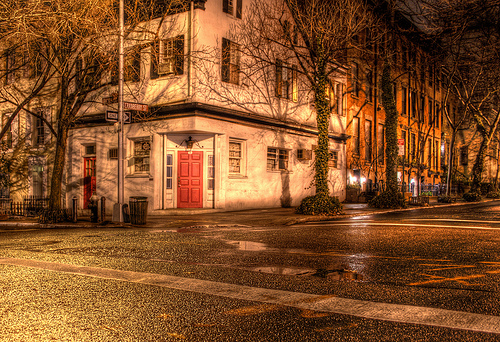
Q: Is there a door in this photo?
A: Yes, there is a door.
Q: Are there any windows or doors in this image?
A: Yes, there is a door.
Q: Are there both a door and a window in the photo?
A: Yes, there are both a door and a window.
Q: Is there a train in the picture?
A: No, there are no trains.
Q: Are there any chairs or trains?
A: No, there are no trains or chairs.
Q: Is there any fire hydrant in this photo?
A: Yes, there is a fire hydrant.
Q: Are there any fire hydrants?
A: Yes, there is a fire hydrant.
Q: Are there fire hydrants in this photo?
A: Yes, there is a fire hydrant.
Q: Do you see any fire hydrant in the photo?
A: Yes, there is a fire hydrant.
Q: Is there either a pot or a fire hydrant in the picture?
A: Yes, there is a fire hydrant.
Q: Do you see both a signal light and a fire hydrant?
A: No, there is a fire hydrant but no traffic lights.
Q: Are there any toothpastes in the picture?
A: No, there are no toothpastes.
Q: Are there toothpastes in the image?
A: No, there are no toothpastes.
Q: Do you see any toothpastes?
A: No, there are no toothpastes.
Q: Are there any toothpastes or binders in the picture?
A: No, there are no toothpastes or binders.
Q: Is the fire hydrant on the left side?
A: Yes, the fire hydrant is on the left of the image.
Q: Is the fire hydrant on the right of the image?
A: No, the fire hydrant is on the left of the image.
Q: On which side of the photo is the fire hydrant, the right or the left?
A: The fire hydrant is on the left of the image.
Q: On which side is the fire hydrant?
A: The fire hydrant is on the left of the image.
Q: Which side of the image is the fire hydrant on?
A: The fire hydrant is on the left of the image.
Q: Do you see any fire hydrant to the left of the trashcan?
A: Yes, there is a fire hydrant to the left of the trashcan.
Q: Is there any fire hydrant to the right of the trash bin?
A: No, the fire hydrant is to the left of the trash bin.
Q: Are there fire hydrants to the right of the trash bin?
A: No, the fire hydrant is to the left of the trash bin.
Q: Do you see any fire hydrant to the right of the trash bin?
A: No, the fire hydrant is to the left of the trash bin.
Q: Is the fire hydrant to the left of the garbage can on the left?
A: Yes, the fire hydrant is to the left of the trash bin.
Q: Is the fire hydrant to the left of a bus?
A: No, the fire hydrant is to the left of the trash bin.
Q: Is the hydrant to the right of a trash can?
A: No, the hydrant is to the left of a trash can.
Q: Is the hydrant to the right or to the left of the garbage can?
A: The hydrant is to the left of the garbage can.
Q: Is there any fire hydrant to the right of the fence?
A: Yes, there is a fire hydrant to the right of the fence.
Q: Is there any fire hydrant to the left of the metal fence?
A: No, the fire hydrant is to the right of the fence.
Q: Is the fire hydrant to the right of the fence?
A: Yes, the fire hydrant is to the right of the fence.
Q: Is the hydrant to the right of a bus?
A: No, the hydrant is to the right of the fence.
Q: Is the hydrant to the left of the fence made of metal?
A: No, the hydrant is to the right of the fence.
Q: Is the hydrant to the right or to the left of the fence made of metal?
A: The hydrant is to the right of the fence.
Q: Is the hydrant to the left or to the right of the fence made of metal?
A: The hydrant is to the right of the fence.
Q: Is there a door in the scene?
A: Yes, there is a door.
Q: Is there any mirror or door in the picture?
A: Yes, there is a door.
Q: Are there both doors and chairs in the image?
A: No, there is a door but no chairs.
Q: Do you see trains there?
A: No, there are no trains.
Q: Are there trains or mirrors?
A: No, there are no trains or mirrors.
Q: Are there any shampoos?
A: No, there are no shampoos.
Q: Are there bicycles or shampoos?
A: No, there are no shampoos or bicycles.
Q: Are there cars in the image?
A: No, there are no cars.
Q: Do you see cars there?
A: No, there are no cars.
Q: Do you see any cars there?
A: No, there are no cars.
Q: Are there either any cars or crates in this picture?
A: No, there are no cars or crates.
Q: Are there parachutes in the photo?
A: No, there are no parachutes.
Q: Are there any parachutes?
A: No, there are no parachutes.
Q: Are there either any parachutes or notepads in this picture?
A: No, there are no parachutes or notepads.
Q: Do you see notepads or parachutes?
A: No, there are no parachutes or notepads.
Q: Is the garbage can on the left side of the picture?
A: Yes, the garbage can is on the left of the image.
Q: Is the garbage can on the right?
A: No, the garbage can is on the left of the image.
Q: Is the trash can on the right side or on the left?
A: The trash can is on the left of the image.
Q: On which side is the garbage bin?
A: The garbage bin is on the left of the image.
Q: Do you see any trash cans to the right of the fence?
A: Yes, there is a trash can to the right of the fence.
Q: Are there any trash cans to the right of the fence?
A: Yes, there is a trash can to the right of the fence.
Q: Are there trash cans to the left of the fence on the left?
A: No, the trash can is to the right of the fence.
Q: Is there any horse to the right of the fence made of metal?
A: No, there is a trash can to the right of the fence.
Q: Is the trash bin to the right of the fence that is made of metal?
A: Yes, the trash bin is to the right of the fence.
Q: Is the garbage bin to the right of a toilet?
A: No, the garbage bin is to the right of the fence.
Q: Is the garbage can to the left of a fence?
A: No, the garbage can is to the right of a fence.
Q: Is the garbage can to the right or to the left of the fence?
A: The garbage can is to the right of the fence.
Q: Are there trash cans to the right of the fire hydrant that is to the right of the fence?
A: Yes, there is a trash can to the right of the fire hydrant.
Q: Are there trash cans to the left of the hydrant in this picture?
A: No, the trash can is to the right of the hydrant.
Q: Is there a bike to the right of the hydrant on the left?
A: No, there is a trash can to the right of the hydrant.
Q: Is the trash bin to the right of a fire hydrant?
A: Yes, the trash bin is to the right of a fire hydrant.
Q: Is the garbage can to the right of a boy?
A: No, the garbage can is to the right of a fire hydrant.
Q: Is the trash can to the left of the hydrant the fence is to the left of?
A: No, the trash can is to the right of the fire hydrant.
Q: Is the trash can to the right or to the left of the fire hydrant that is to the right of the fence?
A: The trash can is to the right of the fire hydrant.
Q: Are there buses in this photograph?
A: No, there are no buses.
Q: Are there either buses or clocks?
A: No, there are no buses or clocks.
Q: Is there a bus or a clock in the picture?
A: No, there are no buses or clocks.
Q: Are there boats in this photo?
A: No, there are no boats.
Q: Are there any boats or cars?
A: No, there are no boats or cars.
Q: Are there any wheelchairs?
A: No, there are no wheelchairs.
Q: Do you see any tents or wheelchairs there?
A: No, there are no wheelchairs or tents.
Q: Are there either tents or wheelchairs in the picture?
A: No, there are no wheelchairs or tents.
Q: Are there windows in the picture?
A: Yes, there are windows.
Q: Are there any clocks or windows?
A: Yes, there are windows.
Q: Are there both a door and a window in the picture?
A: Yes, there are both a window and a door.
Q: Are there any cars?
A: No, there are no cars.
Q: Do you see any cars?
A: No, there are no cars.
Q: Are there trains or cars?
A: No, there are no cars or trains.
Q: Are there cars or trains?
A: No, there are no cars or trains.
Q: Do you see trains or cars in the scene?
A: No, there are no cars or trains.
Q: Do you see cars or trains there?
A: No, there are no cars or trains.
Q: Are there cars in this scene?
A: No, there are no cars.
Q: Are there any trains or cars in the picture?
A: No, there are no cars or trains.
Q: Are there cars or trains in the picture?
A: No, there are no cars or trains.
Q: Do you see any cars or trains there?
A: No, there are no cars or trains.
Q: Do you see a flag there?
A: No, there are no flags.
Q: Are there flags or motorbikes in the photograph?
A: No, there are no flags or motorbikes.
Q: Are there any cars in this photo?
A: No, there are no cars.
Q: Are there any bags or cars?
A: No, there are no cars or bags.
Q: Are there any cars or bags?
A: No, there are no cars or bags.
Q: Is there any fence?
A: Yes, there is a fence.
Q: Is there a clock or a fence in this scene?
A: Yes, there is a fence.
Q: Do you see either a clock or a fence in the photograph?
A: Yes, there is a fence.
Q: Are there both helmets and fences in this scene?
A: No, there is a fence but no helmets.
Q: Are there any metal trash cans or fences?
A: Yes, there is a metal fence.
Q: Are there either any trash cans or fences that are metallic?
A: Yes, the fence is metallic.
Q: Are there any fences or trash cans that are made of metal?
A: Yes, the fence is made of metal.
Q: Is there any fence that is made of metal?
A: Yes, there is a fence that is made of metal.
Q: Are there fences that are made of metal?
A: Yes, there is a fence that is made of metal.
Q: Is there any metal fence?
A: Yes, there is a fence that is made of metal.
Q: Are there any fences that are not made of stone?
A: Yes, there is a fence that is made of metal.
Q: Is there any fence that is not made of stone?
A: Yes, there is a fence that is made of metal.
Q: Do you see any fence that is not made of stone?
A: Yes, there is a fence that is made of metal.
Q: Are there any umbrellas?
A: No, there are no umbrellas.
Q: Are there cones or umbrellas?
A: No, there are no umbrellas or cones.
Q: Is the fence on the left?
A: Yes, the fence is on the left of the image.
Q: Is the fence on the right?
A: No, the fence is on the left of the image.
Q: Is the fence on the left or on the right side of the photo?
A: The fence is on the left of the image.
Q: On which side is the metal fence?
A: The fence is on the left of the image.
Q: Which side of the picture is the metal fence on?
A: The fence is on the left of the image.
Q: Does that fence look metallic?
A: Yes, the fence is metallic.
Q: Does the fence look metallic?
A: Yes, the fence is metallic.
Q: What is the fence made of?
A: The fence is made of metal.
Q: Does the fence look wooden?
A: No, the fence is metallic.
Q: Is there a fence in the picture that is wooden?
A: No, there is a fence but it is metallic.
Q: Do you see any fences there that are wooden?
A: No, there is a fence but it is metallic.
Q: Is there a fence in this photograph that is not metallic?
A: No, there is a fence but it is metallic.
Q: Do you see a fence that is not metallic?
A: No, there is a fence but it is metallic.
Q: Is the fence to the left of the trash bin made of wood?
A: No, the fence is made of metal.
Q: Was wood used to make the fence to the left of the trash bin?
A: No, the fence is made of metal.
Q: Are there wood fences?
A: No, there is a fence but it is made of metal.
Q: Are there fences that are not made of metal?
A: No, there is a fence but it is made of metal.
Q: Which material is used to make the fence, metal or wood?
A: The fence is made of metal.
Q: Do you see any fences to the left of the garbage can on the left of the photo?
A: Yes, there is a fence to the left of the trash bin.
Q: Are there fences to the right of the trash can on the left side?
A: No, the fence is to the left of the garbage can.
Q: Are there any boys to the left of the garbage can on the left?
A: No, there is a fence to the left of the trash bin.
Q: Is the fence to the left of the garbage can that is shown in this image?
A: Yes, the fence is to the left of the garbage can.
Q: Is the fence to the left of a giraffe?
A: No, the fence is to the left of the garbage can.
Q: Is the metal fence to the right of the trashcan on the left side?
A: No, the fence is to the left of the trash can.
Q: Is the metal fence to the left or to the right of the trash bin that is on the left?
A: The fence is to the left of the trash bin.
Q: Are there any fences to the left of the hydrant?
A: Yes, there is a fence to the left of the hydrant.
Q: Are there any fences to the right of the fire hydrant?
A: No, the fence is to the left of the fire hydrant.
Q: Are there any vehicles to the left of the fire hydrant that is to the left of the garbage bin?
A: No, there is a fence to the left of the hydrant.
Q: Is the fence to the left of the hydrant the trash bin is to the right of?
A: Yes, the fence is to the left of the hydrant.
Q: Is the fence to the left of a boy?
A: No, the fence is to the left of the hydrant.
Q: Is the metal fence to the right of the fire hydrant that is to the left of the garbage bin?
A: No, the fence is to the left of the hydrant.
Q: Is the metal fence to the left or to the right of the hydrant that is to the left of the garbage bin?
A: The fence is to the left of the fire hydrant.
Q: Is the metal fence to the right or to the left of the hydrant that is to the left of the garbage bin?
A: The fence is to the left of the fire hydrant.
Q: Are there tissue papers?
A: No, there are no tissue papers.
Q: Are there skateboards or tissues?
A: No, there are no tissues or skateboards.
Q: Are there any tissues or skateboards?
A: No, there are no tissues or skateboards.